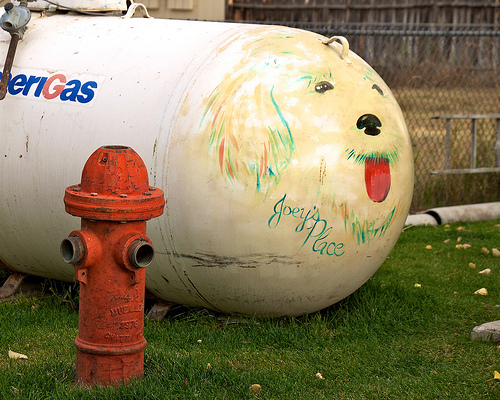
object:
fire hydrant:
[59, 145, 164, 385]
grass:
[15, 235, 497, 400]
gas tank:
[1, 3, 416, 318]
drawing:
[200, 67, 406, 261]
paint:
[343, 111, 402, 202]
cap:
[63, 145, 165, 221]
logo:
[6, 74, 98, 104]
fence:
[347, 16, 500, 210]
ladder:
[430, 115, 499, 176]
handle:
[121, 2, 154, 19]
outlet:
[135, 243, 156, 268]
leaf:
[9, 350, 30, 361]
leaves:
[413, 242, 499, 296]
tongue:
[365, 154, 391, 203]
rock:
[470, 321, 499, 343]